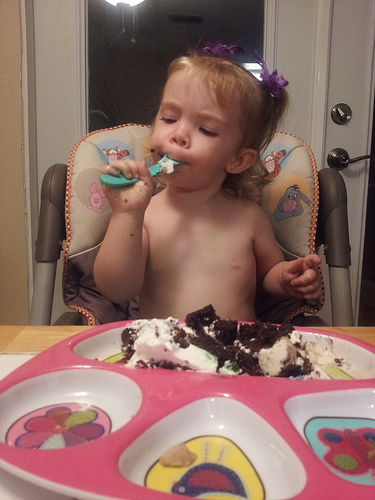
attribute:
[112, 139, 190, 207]
utensil — green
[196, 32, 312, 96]
bow — purple 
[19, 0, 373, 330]
door — silver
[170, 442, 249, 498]
bird — cartoon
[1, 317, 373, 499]
plate — pink, colorful, white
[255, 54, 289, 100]
bows — purple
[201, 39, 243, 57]
bows — purple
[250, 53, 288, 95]
bow — purple 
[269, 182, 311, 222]
animal — cartoon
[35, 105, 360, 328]
chair — high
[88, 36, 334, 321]
child — shirtless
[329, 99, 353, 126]
lock — silver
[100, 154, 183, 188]
spoon — blue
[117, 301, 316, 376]
cake — chocolate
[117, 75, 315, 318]
child — young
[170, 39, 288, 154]
hair — blonde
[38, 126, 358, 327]
chair — high